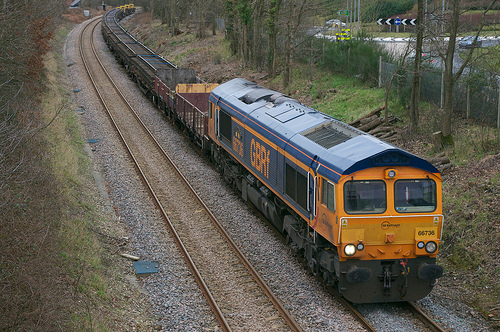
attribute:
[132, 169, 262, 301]
rail — metal